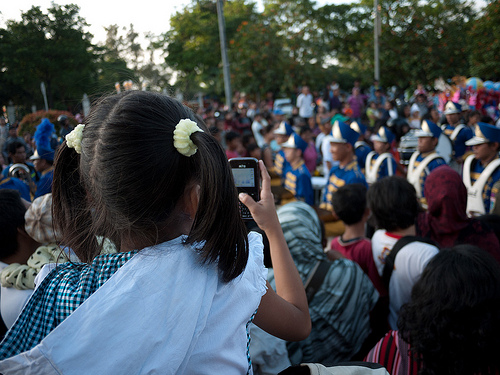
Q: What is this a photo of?
A: Crowd at a parade.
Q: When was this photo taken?
A: In the daytime.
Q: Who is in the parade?
A: A marching band.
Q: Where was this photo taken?
A: On a street.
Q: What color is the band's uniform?
A: Blue and gold.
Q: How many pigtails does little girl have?
A: Two.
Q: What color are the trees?
A: Green.